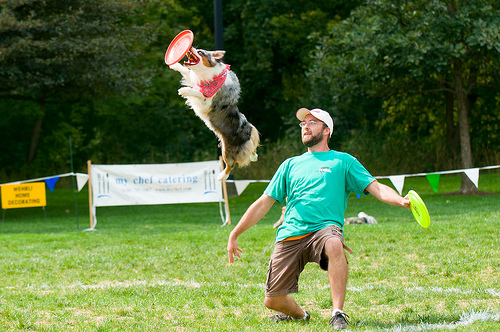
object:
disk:
[407, 189, 430, 228]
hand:
[401, 194, 410, 209]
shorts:
[263, 224, 354, 296]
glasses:
[299, 120, 325, 127]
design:
[316, 166, 331, 173]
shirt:
[262, 148, 372, 243]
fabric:
[196, 64, 231, 98]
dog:
[165, 46, 260, 181]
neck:
[190, 65, 226, 88]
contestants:
[165, 30, 413, 331]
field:
[3, 150, 499, 331]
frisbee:
[165, 28, 196, 64]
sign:
[0, 181, 47, 210]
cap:
[296, 108, 334, 137]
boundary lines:
[0, 278, 495, 295]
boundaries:
[38, 156, 237, 194]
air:
[0, 0, 499, 332]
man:
[226, 108, 410, 332]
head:
[301, 109, 333, 148]